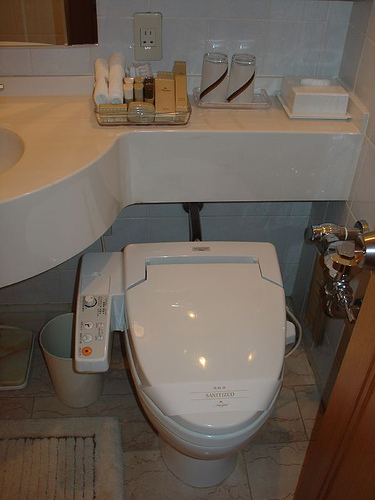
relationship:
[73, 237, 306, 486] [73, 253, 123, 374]
commode has white strip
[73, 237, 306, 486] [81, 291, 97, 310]
commode has control knobs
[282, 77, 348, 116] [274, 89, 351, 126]
tissue box on a tray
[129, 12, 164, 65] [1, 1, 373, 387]
electrical outlet on bathroom wall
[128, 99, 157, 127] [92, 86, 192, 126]
bar of soap on basket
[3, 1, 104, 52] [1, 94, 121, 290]
edge of mirror over bathroom sink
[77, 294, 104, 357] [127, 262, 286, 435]
buttons are next to toilet seat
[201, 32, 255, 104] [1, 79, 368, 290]
glass cups on counter top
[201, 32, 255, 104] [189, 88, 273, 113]
two glasses on tray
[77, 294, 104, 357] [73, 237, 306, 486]
buttons on toilet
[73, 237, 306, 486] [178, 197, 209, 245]
toilet has chrome plumbing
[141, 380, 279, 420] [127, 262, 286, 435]
paper seal over seat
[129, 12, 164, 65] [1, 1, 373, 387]
electrical outlet on wall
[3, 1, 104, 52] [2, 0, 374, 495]
mirror in bathroom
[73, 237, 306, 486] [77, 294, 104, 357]
electronic toilet has controls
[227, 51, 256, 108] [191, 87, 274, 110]
glass sitting on tray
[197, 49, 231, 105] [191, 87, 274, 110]
glass sitting on tray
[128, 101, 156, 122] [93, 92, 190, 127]
bar of soap in basket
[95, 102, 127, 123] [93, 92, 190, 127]
soap in basket